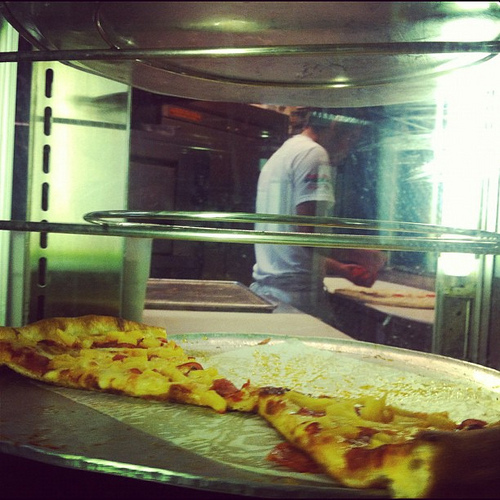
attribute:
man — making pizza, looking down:
[245, 103, 384, 334]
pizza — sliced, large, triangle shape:
[251, 376, 500, 499]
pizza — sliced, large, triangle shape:
[1, 309, 260, 417]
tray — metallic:
[1, 327, 500, 498]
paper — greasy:
[29, 335, 500, 493]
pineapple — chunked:
[283, 388, 318, 411]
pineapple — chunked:
[116, 333, 145, 347]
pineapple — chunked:
[200, 388, 232, 415]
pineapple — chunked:
[424, 415, 458, 431]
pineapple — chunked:
[53, 326, 79, 347]